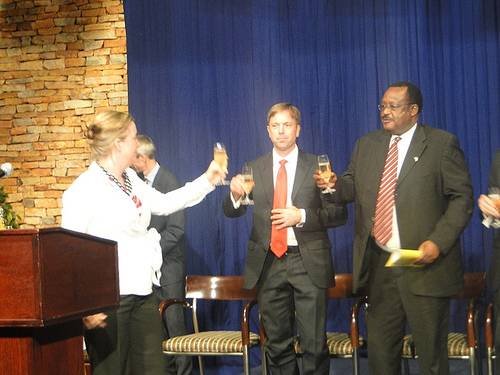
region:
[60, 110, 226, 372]
woman proposing a toast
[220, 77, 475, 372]
men in suits joining a toast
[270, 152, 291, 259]
solid red tie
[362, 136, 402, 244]
red and white striped tie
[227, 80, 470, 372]
men in dark suits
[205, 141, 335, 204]
three champagne glasses full of champagne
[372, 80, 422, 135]
a man wearing glasses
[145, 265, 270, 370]
brown wooden chair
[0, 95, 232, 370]
woman standing behind a brown wooden podium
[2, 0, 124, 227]
brick work on the wall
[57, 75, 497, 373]
People making a toast on stage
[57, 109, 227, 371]
Woman toasting a glass of champagne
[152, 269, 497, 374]
Four metal chairs with cushioned seats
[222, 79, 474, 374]
Two men dressed in black suits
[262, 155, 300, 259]
Hand touching a red suit tie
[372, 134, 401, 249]
Red and white striped necktie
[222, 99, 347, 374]
Man wearing a black suit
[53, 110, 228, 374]
Woman wearing a white shirt and dark slacks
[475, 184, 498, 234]
Hand holding a glass of champagne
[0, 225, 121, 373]
Dark wood podium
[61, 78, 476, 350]
Three people toasting.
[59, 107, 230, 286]
Woman holding up a champage glass.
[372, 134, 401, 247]
Red striped tie around man's neck.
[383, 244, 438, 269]
Book in man's hand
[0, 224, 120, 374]
Wooden speaker's podium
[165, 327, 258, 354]
Striped cushion on the chair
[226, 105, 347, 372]
Man wearing a suit and red tie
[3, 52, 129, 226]
Stone on the wall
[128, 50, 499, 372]
Blue curtain behind people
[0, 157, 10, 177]
Tip of a microphone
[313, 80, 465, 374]
black man in a suit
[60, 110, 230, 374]
woman holding a champagne glass to the men behind her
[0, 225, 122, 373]
wooden podium in front of the woman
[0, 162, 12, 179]
silver and black microphone above the podium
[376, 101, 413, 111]
eyeglasses worn by the black man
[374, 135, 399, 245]
striped red tie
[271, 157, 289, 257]
solid red tie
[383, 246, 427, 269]
folded papers in the man's hand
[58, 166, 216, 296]
white jacket worn by the woman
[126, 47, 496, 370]
large blue curtain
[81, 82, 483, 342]
people toasting each other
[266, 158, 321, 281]
a plain red tie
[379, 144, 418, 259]
a red and white striped tie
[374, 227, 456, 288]
a man holding a book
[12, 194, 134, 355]
podium for speakers to talk at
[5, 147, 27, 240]
the microphone at the podium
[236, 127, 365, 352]
a man holding a glass of wine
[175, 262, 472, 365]
the wooden chairs on the stage for people to sit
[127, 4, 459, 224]
the blue curtain on the stage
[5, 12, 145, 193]
the brick wall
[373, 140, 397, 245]
dark red and white tie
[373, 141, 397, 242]
striped neck tie on man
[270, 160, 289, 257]
solid red tie on man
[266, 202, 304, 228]
hand holding red tie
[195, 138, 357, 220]
three glasses of champagne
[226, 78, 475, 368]
two men in black suits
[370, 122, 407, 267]
a red striped tie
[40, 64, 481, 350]
a group of people holding champagne glasses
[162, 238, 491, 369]
a row of chairs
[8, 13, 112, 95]
a section of brick wall